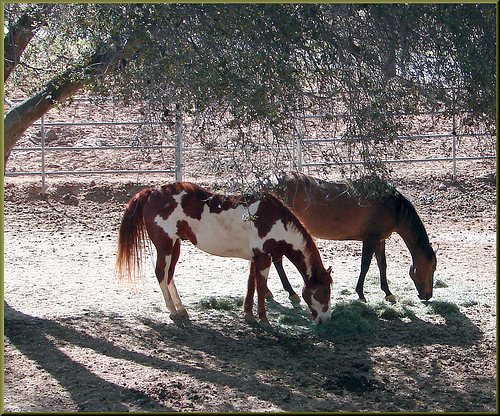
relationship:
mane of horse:
[267, 195, 325, 277] [113, 177, 337, 327]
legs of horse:
[240, 254, 306, 320] [106, 172, 340, 348]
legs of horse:
[151, 240, 201, 320] [113, 177, 337, 327]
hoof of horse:
[242, 311, 275, 331] [113, 177, 337, 327]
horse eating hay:
[102, 174, 458, 327] [310, 294, 371, 339]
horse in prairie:
[102, 174, 458, 327] [15, 88, 465, 414]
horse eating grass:
[135, 174, 458, 327] [214, 296, 454, 358]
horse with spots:
[102, 174, 458, 327] [161, 180, 221, 220]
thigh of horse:
[135, 187, 191, 315] [126, 162, 376, 324]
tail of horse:
[116, 163, 172, 296] [96, 181, 364, 313]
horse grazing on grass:
[113, 177, 337, 327] [4, 234, 498, 410]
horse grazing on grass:
[253, 169, 438, 319] [4, 234, 498, 410]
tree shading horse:
[2, 9, 498, 334] [113, 182, 329, 336]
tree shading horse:
[2, 9, 498, 334] [244, 156, 451, 330]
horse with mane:
[253, 169, 438, 319] [370, 187, 437, 256]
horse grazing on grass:
[113, 182, 329, 336] [124, 262, 491, 376]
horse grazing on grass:
[253, 169, 438, 319] [124, 262, 491, 376]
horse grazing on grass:
[113, 182, 329, 336] [130, 258, 484, 387]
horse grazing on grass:
[253, 169, 438, 319] [130, 258, 484, 387]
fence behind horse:
[4, 84, 498, 198] [113, 177, 337, 327]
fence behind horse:
[4, 84, 498, 198] [253, 176, 451, 312]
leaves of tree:
[17, 5, 487, 166] [6, 5, 493, 365]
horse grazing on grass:
[113, 182, 329, 336] [161, 265, 486, 386]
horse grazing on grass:
[253, 169, 438, 319] [161, 265, 486, 386]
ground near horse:
[2, 191, 492, 318] [113, 177, 337, 327]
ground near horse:
[2, 191, 492, 318] [253, 169, 438, 319]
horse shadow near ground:
[330, 287, 479, 357] [1, 180, 497, 414]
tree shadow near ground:
[4, 296, 402, 414] [1, 180, 497, 414]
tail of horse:
[116, 178, 152, 281] [113, 182, 329, 336]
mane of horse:
[386, 191, 446, 260] [253, 169, 438, 319]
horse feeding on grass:
[113, 182, 329, 336] [215, 262, 495, 367]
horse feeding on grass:
[253, 169, 438, 319] [195, 260, 493, 369]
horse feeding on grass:
[102, 174, 458, 327] [215, 341, 322, 387]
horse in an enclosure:
[102, 174, 458, 327] [49, 106, 133, 173]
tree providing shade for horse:
[2, 9, 497, 172] [102, 174, 458, 327]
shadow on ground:
[34, 338, 153, 404] [195, 336, 320, 394]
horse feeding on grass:
[102, 174, 458, 327] [210, 309, 383, 368]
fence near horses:
[4, 84, 498, 188] [82, 146, 426, 338]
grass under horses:
[112, 316, 426, 366] [80, 136, 466, 342]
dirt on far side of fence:
[89, 128, 144, 169] [98, 87, 204, 152]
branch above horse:
[358, 44, 438, 93] [102, 174, 458, 327]